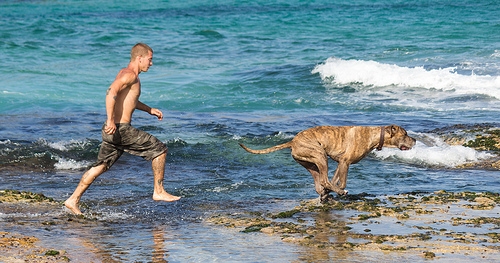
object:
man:
[61, 43, 182, 214]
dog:
[237, 124, 416, 197]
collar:
[374, 125, 387, 153]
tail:
[237, 141, 292, 155]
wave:
[311, 54, 500, 108]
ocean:
[0, 0, 499, 220]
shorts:
[90, 123, 169, 170]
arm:
[104, 72, 138, 123]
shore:
[0, 120, 499, 262]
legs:
[335, 159, 356, 189]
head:
[381, 125, 417, 151]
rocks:
[0, 151, 58, 173]